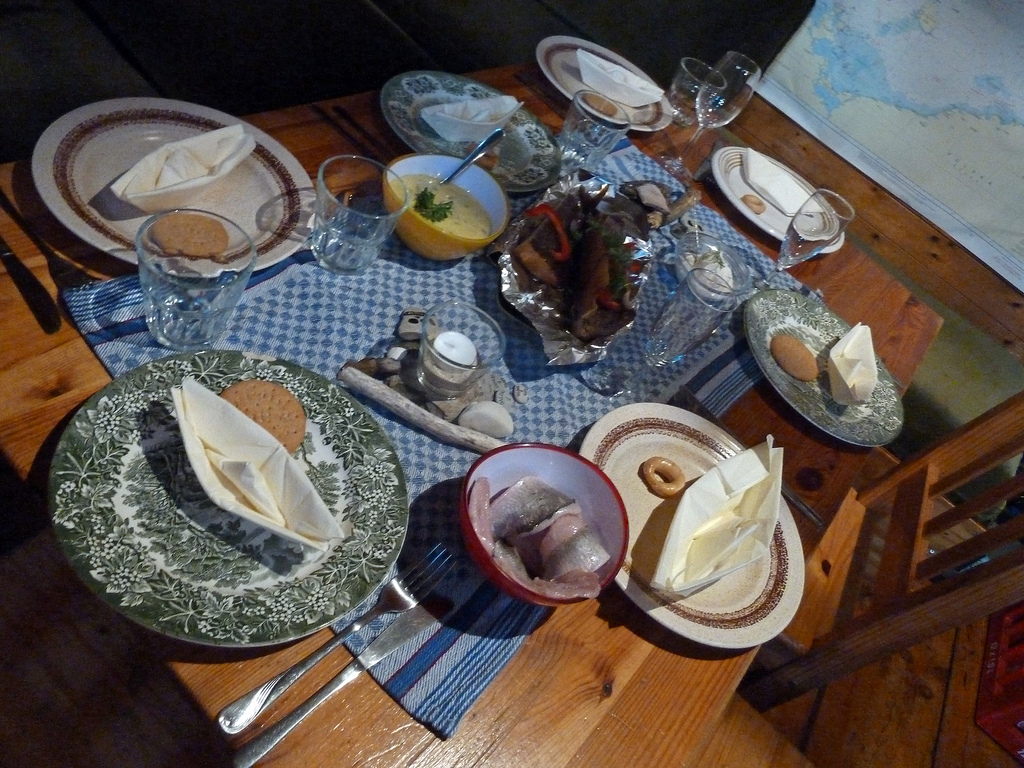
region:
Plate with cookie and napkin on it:
[25, 335, 443, 649]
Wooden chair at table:
[824, 386, 1021, 678]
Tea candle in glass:
[407, 303, 507, 403]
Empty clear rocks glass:
[107, 211, 266, 341]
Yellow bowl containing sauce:
[369, 145, 534, 275]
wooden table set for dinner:
[3, 86, 964, 704]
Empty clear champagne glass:
[762, 177, 855, 346]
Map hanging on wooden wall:
[735, 13, 1021, 289]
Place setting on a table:
[21, 335, 512, 754]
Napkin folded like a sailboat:
[78, 118, 276, 221]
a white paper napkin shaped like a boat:
[169, 374, 340, 558]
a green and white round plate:
[46, 353, 410, 652]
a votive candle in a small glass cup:
[413, 301, 502, 401]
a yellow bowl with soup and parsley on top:
[389, 148, 511, 259]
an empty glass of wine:
[756, 181, 854, 309]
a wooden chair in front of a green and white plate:
[743, 286, 1022, 719]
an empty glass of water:
[311, 151, 411, 278]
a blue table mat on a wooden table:
[0, 56, 946, 756]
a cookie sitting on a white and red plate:
[29, 94, 314, 276]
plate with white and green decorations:
[49, 339, 416, 652]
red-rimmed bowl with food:
[456, 427, 631, 615]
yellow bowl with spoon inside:
[387, 122, 518, 262]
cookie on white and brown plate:
[30, 84, 321, 274]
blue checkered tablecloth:
[71, 115, 817, 736]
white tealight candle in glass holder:
[413, 296, 506, 398]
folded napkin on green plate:
[735, 279, 910, 451]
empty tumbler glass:
[304, 147, 407, 274]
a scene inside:
[12, 44, 1021, 765]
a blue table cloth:
[45, 89, 848, 756]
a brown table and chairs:
[9, 85, 958, 763]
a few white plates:
[19, 31, 939, 674]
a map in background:
[742, 19, 1015, 334]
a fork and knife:
[192, 507, 505, 764]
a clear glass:
[118, 177, 275, 383]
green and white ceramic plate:
[42, 337, 413, 661]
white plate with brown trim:
[578, 403, 804, 651]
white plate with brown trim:
[29, 100, 324, 281]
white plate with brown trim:
[534, 33, 675, 138]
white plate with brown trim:
[702, 140, 845, 255]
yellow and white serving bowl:
[380, 153, 510, 262]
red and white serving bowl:
[461, 435, 635, 617]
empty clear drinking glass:
[132, 204, 260, 351]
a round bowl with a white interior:
[457, 439, 631, 608]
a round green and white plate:
[44, 348, 409, 655]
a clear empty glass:
[133, 205, 255, 354]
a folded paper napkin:
[163, 367, 347, 558]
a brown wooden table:
[2, 54, 945, 764]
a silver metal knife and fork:
[212, 538, 460, 766]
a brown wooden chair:
[738, 394, 1023, 712]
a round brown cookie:
[212, 375, 310, 451]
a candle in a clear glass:
[413, 301, 505, 401]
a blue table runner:
[57, 129, 823, 740]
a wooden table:
[536, 651, 619, 727]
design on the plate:
[136, 530, 244, 617]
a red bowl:
[474, 440, 614, 609]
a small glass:
[316, 152, 409, 242]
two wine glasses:
[670, 48, 773, 102]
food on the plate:
[647, 453, 690, 496]